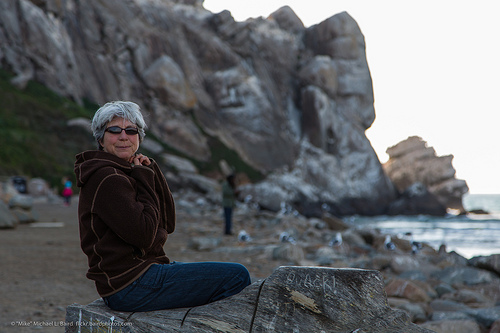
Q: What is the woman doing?
A: Woman sitting on a rock.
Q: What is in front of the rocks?
A: A body of water.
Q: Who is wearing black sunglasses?
A: The woman.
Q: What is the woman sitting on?
A: A large rock.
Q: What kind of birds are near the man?
A: Seagulls.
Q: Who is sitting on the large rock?
A: The woman.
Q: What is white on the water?
A: White caps.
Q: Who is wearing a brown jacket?
A: The woman.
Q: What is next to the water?
A: The shoreline.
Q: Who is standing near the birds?
A: The man.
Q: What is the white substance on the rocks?
A: Frost.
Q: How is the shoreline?
A: This is a rcoky shore line.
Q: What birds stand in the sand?
A: Seagulls are in the sand.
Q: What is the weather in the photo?
A: Cloudy and gray and not very warm.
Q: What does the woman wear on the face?
A: Sunglasses are worn.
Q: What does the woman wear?
A: Wears long sleeves and long pants.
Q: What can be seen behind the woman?
A: A large rock formation.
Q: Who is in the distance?
A: People are walking on the beach.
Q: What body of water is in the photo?
A: The ocean.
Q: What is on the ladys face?
A: Sunglasses.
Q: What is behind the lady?
A: Gray rocks.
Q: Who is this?
A: A woman.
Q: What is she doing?
A: Sitting.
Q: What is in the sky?
A: Nothing.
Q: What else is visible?
A: Nothing.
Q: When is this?
A: Daytime.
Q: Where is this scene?
A: At a rocky beach.